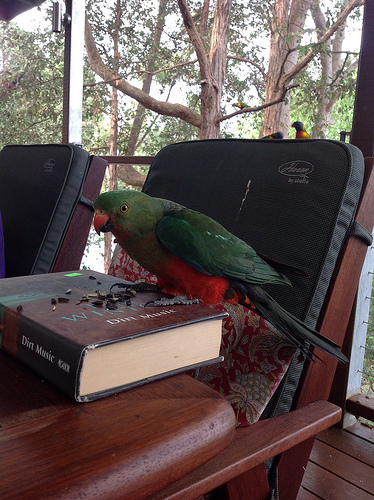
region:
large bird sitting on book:
[82, 169, 307, 369]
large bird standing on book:
[74, 155, 340, 405]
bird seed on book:
[50, 273, 109, 314]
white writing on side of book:
[19, 337, 89, 391]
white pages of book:
[80, 321, 217, 401]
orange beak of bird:
[83, 213, 108, 238]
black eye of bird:
[121, 203, 125, 210]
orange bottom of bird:
[146, 263, 224, 312]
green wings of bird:
[154, 205, 299, 285]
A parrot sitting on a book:
[93, 187, 351, 369]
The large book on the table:
[0, 267, 229, 404]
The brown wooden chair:
[0, 139, 373, 499]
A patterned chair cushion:
[101, 240, 298, 426]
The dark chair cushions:
[106, 140, 372, 497]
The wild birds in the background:
[231, 100, 308, 140]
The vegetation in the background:
[0, 0, 373, 191]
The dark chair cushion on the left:
[0, 141, 89, 276]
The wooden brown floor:
[290, 420, 371, 498]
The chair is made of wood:
[9, 403, 258, 495]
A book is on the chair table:
[1, 265, 228, 403]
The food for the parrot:
[36, 271, 146, 321]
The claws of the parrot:
[106, 271, 205, 311]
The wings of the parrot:
[156, 205, 293, 293]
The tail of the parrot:
[247, 285, 355, 377]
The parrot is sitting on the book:
[77, 171, 355, 380]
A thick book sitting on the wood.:
[1, 268, 228, 403]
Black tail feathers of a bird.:
[238, 279, 350, 368]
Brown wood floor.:
[296, 423, 372, 498]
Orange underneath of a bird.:
[158, 256, 254, 307]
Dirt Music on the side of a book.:
[19, 333, 57, 363]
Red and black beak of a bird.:
[92, 209, 111, 238]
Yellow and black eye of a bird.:
[119, 202, 129, 214]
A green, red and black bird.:
[92, 189, 348, 367]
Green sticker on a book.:
[64, 271, 81, 278]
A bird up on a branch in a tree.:
[231, 100, 242, 111]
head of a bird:
[77, 170, 171, 251]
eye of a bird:
[116, 193, 142, 214]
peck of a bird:
[89, 219, 120, 240]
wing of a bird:
[210, 237, 293, 279]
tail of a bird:
[243, 291, 358, 361]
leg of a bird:
[146, 290, 207, 316]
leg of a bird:
[109, 260, 174, 294]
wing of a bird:
[151, 202, 300, 288]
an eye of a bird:
[116, 198, 135, 219]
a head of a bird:
[74, 179, 149, 243]